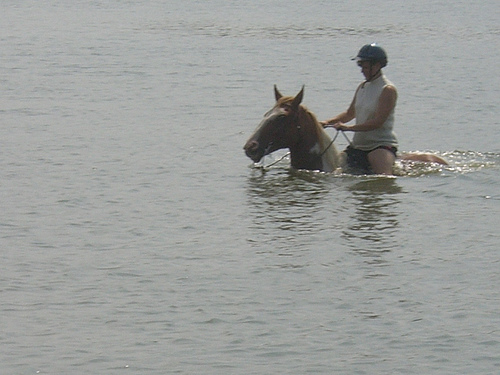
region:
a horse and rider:
[243, 42, 447, 178]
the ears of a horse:
[268, 85, 307, 106]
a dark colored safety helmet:
[350, 43, 388, 65]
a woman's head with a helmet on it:
[354, 44, 389, 78]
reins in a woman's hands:
[319, 117, 350, 131]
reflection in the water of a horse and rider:
[243, 175, 414, 258]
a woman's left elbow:
[367, 118, 384, 130]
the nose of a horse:
[242, 139, 254, 155]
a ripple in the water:
[400, 150, 497, 175]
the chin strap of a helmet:
[362, 58, 382, 79]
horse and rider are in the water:
[244, 37, 462, 189]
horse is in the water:
[241, 85, 452, 186]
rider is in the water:
[322, 38, 404, 176]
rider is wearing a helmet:
[321, 38, 403, 173]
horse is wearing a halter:
[238, 83, 335, 177]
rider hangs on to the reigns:
[311, 41, 402, 176]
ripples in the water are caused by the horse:
[260, 144, 497, 186]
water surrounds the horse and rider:
[0, 3, 497, 374]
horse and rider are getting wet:
[241, 37, 449, 188]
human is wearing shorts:
[315, 41, 409, 181]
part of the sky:
[273, 265, 286, 290]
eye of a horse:
[283, 120, 287, 127]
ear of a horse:
[301, 95, 310, 100]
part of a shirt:
[374, 115, 384, 127]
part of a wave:
[318, 293, 342, 319]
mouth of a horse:
[248, 150, 268, 164]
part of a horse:
[298, 136, 315, 151]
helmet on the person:
[348, 28, 403, 82]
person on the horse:
[326, 23, 426, 166]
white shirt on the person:
[336, 74, 402, 154]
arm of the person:
[336, 88, 399, 145]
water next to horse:
[249, 193, 333, 268]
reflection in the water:
[238, 178, 316, 231]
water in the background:
[72, 5, 176, 81]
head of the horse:
[236, 70, 328, 177]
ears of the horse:
[260, 68, 320, 115]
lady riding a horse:
[199, 35, 427, 226]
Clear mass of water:
[89, 330, 256, 357]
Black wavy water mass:
[248, 144, 332, 261]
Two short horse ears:
[269, 80, 307, 101]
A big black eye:
[274, 110, 291, 129]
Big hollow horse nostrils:
[241, 137, 265, 154]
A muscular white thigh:
[368, 142, 394, 176]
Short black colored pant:
[343, 145, 403, 162]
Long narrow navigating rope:
[323, 131, 335, 158]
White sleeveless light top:
[357, 89, 377, 118]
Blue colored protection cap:
[343, 40, 398, 67]